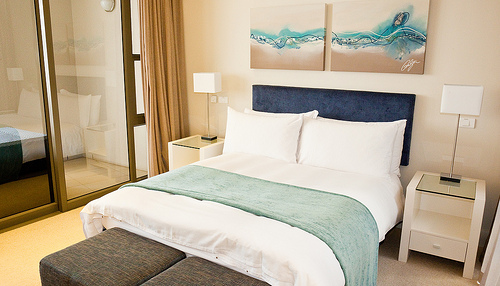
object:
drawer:
[407, 229, 468, 263]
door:
[0, 0, 174, 230]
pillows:
[56, 93, 96, 129]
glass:
[1, 0, 129, 218]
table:
[396, 170, 488, 280]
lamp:
[192, 72, 223, 141]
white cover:
[82, 148, 405, 286]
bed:
[79, 84, 417, 286]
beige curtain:
[136, 1, 188, 178]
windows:
[0, 0, 55, 231]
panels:
[50, 1, 130, 207]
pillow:
[294, 114, 409, 179]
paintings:
[246, 0, 328, 73]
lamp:
[438, 84, 486, 185]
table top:
[407, 170, 488, 203]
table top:
[170, 134, 225, 153]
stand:
[396, 171, 488, 278]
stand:
[166, 134, 224, 172]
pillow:
[220, 106, 304, 163]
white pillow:
[241, 107, 320, 161]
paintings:
[326, 1, 430, 74]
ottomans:
[139, 254, 267, 286]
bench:
[38, 226, 188, 286]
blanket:
[81, 155, 405, 286]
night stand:
[166, 134, 224, 173]